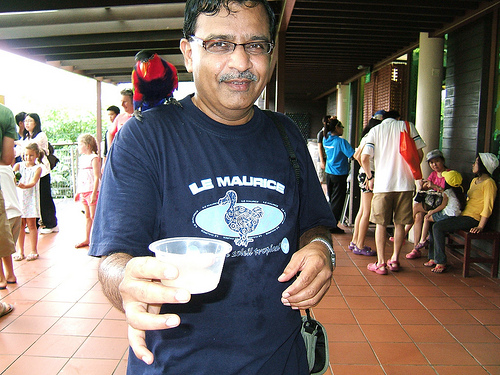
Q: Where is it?
A: This is at the pavement.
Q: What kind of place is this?
A: It is a pavement.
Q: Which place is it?
A: It is a pavement.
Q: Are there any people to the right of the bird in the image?
A: No, the person is to the left of the bird.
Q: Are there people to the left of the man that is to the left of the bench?
A: Yes, there is a person to the left of the man.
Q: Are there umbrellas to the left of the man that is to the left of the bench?
A: No, there is a person to the left of the man.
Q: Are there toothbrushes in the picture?
A: No, there are no toothbrushes.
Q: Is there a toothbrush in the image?
A: No, there are no toothbrushes.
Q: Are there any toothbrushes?
A: No, there are no toothbrushes.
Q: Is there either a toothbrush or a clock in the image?
A: No, there are no toothbrushes or clocks.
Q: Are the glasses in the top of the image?
A: Yes, the glasses are in the top of the image.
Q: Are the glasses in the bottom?
A: No, the glasses are in the top of the image.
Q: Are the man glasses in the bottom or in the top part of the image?
A: The glasses are in the top of the image.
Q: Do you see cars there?
A: No, there are no cars.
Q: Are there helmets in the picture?
A: No, there are no helmets.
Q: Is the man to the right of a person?
A: Yes, the man is to the right of a person.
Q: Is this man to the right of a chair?
A: No, the man is to the right of a person.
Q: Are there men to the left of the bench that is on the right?
A: Yes, there is a man to the left of the bench.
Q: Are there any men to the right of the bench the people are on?
A: No, the man is to the left of the bench.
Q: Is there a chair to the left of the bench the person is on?
A: No, there is a man to the left of the bench.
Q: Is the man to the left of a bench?
A: Yes, the man is to the left of a bench.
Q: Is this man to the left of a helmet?
A: No, the man is to the left of a bench.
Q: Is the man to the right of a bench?
A: No, the man is to the left of a bench.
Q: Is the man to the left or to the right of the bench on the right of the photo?
A: The man is to the left of the bench.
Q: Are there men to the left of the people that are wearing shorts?
A: Yes, there is a man to the left of the people.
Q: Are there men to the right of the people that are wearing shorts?
A: No, the man is to the left of the people.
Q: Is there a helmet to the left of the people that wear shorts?
A: No, there is a man to the left of the people.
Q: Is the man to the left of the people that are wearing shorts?
A: Yes, the man is to the left of the people.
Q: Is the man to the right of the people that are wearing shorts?
A: No, the man is to the left of the people.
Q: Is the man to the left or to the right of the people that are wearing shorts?
A: The man is to the left of the people.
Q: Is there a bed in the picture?
A: No, there are no beds.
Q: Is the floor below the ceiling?
A: Yes, the floor is below the ceiling.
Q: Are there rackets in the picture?
A: No, there are no rackets.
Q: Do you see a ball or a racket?
A: No, there are no rackets or balls.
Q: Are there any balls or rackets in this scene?
A: No, there are no rackets or balls.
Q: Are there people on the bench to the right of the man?
A: Yes, there are people on the bench.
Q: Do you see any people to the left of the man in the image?
A: No, the people are to the right of the man.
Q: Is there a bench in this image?
A: Yes, there is a bench.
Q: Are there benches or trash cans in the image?
A: Yes, there is a bench.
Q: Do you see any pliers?
A: No, there are no pliers.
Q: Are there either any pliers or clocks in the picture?
A: No, there are no pliers or clocks.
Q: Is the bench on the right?
A: Yes, the bench is on the right of the image.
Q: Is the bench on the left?
A: No, the bench is on the right of the image.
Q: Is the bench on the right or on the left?
A: The bench is on the right of the image.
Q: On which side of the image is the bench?
A: The bench is on the right of the image.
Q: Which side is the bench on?
A: The bench is on the right of the image.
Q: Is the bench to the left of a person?
A: No, the bench is to the right of a person.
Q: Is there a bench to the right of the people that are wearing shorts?
A: Yes, there is a bench to the right of the people.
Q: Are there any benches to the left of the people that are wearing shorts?
A: No, the bench is to the right of the people.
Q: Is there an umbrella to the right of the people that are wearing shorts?
A: No, there is a bench to the right of the people.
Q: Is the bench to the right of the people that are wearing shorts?
A: Yes, the bench is to the right of the people.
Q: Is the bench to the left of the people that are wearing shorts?
A: No, the bench is to the right of the people.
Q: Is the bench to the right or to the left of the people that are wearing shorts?
A: The bench is to the right of the people.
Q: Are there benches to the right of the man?
A: Yes, there is a bench to the right of the man.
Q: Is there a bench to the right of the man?
A: Yes, there is a bench to the right of the man.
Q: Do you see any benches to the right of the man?
A: Yes, there is a bench to the right of the man.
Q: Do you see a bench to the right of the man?
A: Yes, there is a bench to the right of the man.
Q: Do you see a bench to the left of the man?
A: No, the bench is to the right of the man.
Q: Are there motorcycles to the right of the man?
A: No, there is a bench to the right of the man.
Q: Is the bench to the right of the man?
A: Yes, the bench is to the right of the man.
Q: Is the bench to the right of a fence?
A: No, the bench is to the right of the man.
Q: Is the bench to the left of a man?
A: No, the bench is to the right of a man.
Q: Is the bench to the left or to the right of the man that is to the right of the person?
A: The bench is to the right of the man.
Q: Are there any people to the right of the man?
A: Yes, there is a person to the right of the man.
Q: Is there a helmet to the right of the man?
A: No, there is a person to the right of the man.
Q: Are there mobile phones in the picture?
A: No, there are no mobile phones.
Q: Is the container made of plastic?
A: Yes, the container is made of plastic.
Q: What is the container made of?
A: The container is made of plastic.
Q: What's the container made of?
A: The container is made of plastic.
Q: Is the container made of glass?
A: No, the container is made of plastic.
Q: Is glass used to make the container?
A: No, the container is made of plastic.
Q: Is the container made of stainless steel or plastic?
A: The container is made of plastic.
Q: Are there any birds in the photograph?
A: Yes, there is a bird.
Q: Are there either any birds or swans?
A: Yes, there is a bird.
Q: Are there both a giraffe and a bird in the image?
A: No, there is a bird but no giraffes.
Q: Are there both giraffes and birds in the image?
A: No, there is a bird but no giraffes.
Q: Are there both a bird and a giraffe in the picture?
A: No, there is a bird but no giraffes.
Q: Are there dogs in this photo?
A: No, there are no dogs.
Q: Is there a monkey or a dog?
A: No, there are no dogs or monkeys.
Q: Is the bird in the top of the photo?
A: Yes, the bird is in the top of the image.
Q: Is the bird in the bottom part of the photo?
A: No, the bird is in the top of the image.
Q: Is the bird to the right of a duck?
A: No, the bird is to the right of a person.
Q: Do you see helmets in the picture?
A: No, there are no helmets.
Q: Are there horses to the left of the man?
A: No, there is a person to the left of the man.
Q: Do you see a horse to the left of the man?
A: No, there is a person to the left of the man.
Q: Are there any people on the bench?
A: Yes, there is a person on the bench.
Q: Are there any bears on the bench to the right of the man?
A: No, there is a person on the bench.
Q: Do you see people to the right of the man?
A: Yes, there is a person to the right of the man.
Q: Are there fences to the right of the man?
A: No, there is a person to the right of the man.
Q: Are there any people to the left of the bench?
A: Yes, there is a person to the left of the bench.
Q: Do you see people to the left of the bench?
A: Yes, there is a person to the left of the bench.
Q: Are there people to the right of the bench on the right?
A: No, the person is to the left of the bench.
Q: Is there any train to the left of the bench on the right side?
A: No, there is a person to the left of the bench.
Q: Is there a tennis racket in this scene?
A: No, there are no rackets.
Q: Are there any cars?
A: No, there are no cars.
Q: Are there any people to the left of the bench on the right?
A: Yes, there are people to the left of the bench.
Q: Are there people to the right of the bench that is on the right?
A: No, the people are to the left of the bench.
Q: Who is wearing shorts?
A: The people are wearing shorts.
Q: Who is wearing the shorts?
A: The people are wearing shorts.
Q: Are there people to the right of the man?
A: Yes, there are people to the right of the man.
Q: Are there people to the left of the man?
A: No, the people are to the right of the man.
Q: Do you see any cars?
A: No, there are no cars.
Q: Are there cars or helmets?
A: No, there are no cars or helmets.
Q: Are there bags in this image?
A: Yes, there is a bag.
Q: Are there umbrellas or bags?
A: Yes, there is a bag.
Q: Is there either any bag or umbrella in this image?
A: Yes, there is a bag.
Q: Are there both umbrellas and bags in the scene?
A: No, there is a bag but no umbrellas.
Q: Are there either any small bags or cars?
A: Yes, there is a small bag.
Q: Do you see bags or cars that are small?
A: Yes, the bag is small.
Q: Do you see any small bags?
A: Yes, there is a small bag.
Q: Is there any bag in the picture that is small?
A: Yes, there is a bag that is small.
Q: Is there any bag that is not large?
A: Yes, there is a small bag.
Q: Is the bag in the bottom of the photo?
A: Yes, the bag is in the bottom of the image.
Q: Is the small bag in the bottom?
A: Yes, the bag is in the bottom of the image.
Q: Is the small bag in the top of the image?
A: No, the bag is in the bottom of the image.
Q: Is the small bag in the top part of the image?
A: No, the bag is in the bottom of the image.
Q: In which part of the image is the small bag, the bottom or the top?
A: The bag is in the bottom of the image.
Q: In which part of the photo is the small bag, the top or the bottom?
A: The bag is in the bottom of the image.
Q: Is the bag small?
A: Yes, the bag is small.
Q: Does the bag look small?
A: Yes, the bag is small.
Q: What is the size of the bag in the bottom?
A: The bag is small.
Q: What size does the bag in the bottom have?
A: The bag has small size.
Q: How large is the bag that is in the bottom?
A: The bag is small.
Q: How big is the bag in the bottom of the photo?
A: The bag is small.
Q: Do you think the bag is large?
A: No, the bag is small.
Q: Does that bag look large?
A: No, the bag is small.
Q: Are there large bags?
A: No, there is a bag but it is small.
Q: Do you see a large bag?
A: No, there is a bag but it is small.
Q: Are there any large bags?
A: No, there is a bag but it is small.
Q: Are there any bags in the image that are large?
A: No, there is a bag but it is small.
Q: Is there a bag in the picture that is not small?
A: No, there is a bag but it is small.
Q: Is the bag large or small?
A: The bag is small.